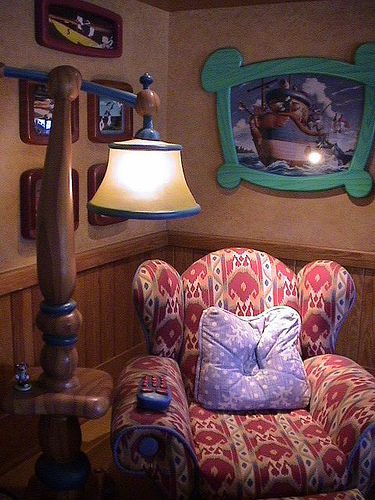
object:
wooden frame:
[35, 2, 123, 58]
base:
[24, 414, 95, 500]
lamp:
[0, 55, 200, 497]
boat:
[227, 68, 366, 181]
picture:
[222, 70, 372, 177]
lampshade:
[85, 133, 204, 222]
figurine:
[9, 355, 37, 395]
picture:
[227, 67, 368, 180]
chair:
[110, 245, 374, 498]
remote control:
[134, 372, 174, 414]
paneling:
[0, 245, 116, 364]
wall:
[3, 5, 178, 279]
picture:
[94, 90, 130, 141]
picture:
[47, 2, 116, 50]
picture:
[33, 84, 56, 134]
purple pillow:
[194, 304, 313, 415]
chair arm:
[111, 353, 193, 490]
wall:
[163, 0, 363, 242]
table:
[2, 360, 116, 499]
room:
[0, 0, 375, 500]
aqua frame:
[193, 45, 374, 208]